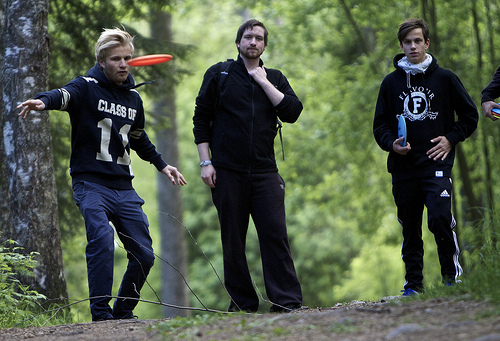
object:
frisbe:
[123, 44, 176, 73]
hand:
[247, 67, 267, 82]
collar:
[233, 56, 251, 74]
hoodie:
[367, 64, 476, 143]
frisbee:
[385, 115, 417, 146]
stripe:
[443, 195, 460, 276]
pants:
[376, 183, 466, 288]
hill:
[184, 279, 459, 341]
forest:
[18, 1, 493, 301]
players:
[372, 19, 461, 302]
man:
[198, 15, 306, 310]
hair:
[234, 17, 269, 42]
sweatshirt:
[20, 79, 188, 189]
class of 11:
[94, 96, 145, 176]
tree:
[0, 0, 63, 252]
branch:
[70, 290, 126, 309]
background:
[41, 18, 489, 166]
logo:
[218, 65, 234, 75]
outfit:
[195, 60, 301, 297]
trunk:
[0, 131, 61, 294]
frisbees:
[492, 107, 500, 113]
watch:
[188, 158, 220, 164]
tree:
[289, 14, 368, 186]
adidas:
[434, 188, 457, 203]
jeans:
[78, 186, 154, 304]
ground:
[70, 317, 242, 341]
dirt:
[328, 307, 478, 331]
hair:
[92, 19, 119, 53]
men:
[37, 28, 184, 316]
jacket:
[188, 66, 310, 147]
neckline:
[233, 55, 278, 70]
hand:
[476, 101, 500, 118]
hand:
[421, 132, 454, 164]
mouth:
[246, 46, 262, 53]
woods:
[469, 9, 489, 72]